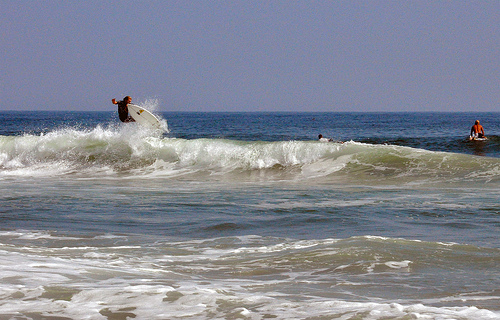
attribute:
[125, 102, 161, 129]
surfboard — white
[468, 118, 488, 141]
man — bare chested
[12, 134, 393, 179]
wave — white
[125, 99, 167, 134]
surfboard — white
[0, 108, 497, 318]
water — calm, blue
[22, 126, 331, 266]
wave — white-capped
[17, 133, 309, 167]
capped wave — white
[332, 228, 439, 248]
wave — white capped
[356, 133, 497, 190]
waves — little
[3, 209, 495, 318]
waves — little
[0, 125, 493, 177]
wave — white-capped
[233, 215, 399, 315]
waves — little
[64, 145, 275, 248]
waves — little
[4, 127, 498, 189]
wave — white-capped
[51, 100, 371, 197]
waves — little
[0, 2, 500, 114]
sky — grayish, pictured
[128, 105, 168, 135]
surfboard — pictured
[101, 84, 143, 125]
man — surfing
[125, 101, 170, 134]
board — white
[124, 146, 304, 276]
waves — little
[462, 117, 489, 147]
man — light-skinned